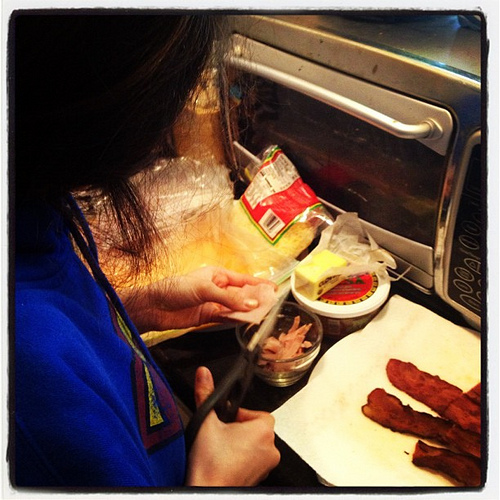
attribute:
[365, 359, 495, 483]
bacon strips — delicious, cooked, red, brown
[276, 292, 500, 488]
cutting board — white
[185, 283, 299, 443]
scissors — metal, black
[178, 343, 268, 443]
handle — black, plastic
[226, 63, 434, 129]
bar handle — horizontal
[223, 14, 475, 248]
oven — gray, metal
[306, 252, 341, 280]
butter stick — yellow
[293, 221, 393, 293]
wrapper — white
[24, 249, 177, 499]
shirt — blue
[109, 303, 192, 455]
emblem — red, yellow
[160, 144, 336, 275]
bag — plastic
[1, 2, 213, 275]
hair — dark, black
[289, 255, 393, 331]
sa container — round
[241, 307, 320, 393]
glass container — small, round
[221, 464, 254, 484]
skin — light colored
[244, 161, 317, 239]
food label — red, gree, white,